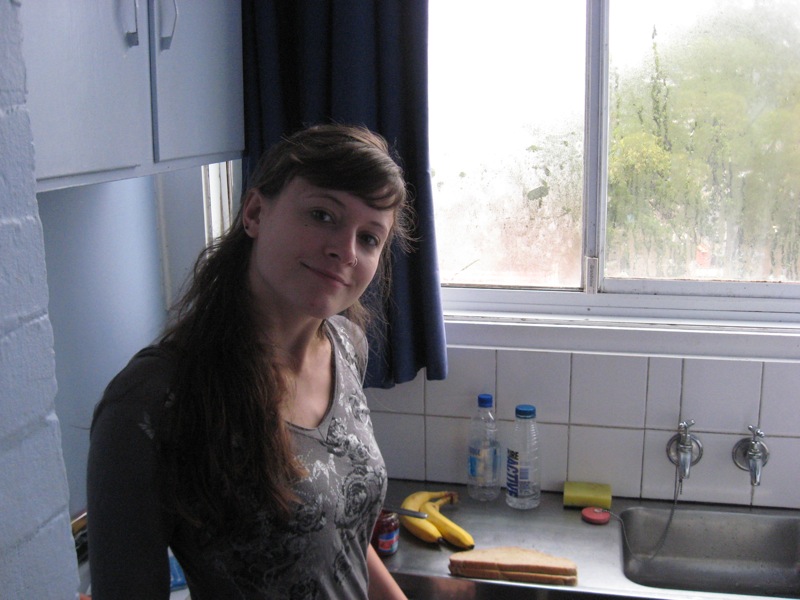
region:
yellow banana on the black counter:
[398, 482, 447, 546]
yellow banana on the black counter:
[427, 490, 479, 551]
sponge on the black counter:
[548, 474, 620, 507]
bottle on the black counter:
[506, 395, 538, 510]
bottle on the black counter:
[468, 392, 497, 499]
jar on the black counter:
[373, 503, 399, 551]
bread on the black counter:
[448, 544, 581, 587]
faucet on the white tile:
[665, 415, 708, 484]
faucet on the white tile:
[737, 426, 772, 490]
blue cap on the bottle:
[510, 399, 545, 421]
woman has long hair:
[87, 122, 410, 595]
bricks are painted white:
[5, 2, 85, 599]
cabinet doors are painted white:
[19, 2, 246, 194]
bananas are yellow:
[399, 483, 480, 557]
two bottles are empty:
[458, 386, 550, 514]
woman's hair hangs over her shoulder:
[149, 123, 406, 557]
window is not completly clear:
[603, 2, 796, 282]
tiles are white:
[362, 345, 799, 510]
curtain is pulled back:
[241, 3, 451, 389]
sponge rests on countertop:
[556, 472, 620, 512]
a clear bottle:
[462, 387, 508, 512]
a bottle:
[502, 402, 544, 506]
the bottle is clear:
[504, 404, 549, 506]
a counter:
[553, 529, 587, 550]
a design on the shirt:
[311, 460, 384, 529]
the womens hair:
[201, 384, 252, 453]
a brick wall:
[16, 427, 65, 543]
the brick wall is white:
[9, 438, 63, 540]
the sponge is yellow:
[567, 480, 609, 502]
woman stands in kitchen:
[86, 122, 418, 596]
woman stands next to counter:
[85, 120, 411, 599]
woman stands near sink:
[82, 120, 405, 599]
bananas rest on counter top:
[399, 482, 476, 560]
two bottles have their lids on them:
[465, 388, 548, 513]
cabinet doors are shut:
[18, 1, 253, 188]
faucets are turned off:
[668, 417, 776, 494]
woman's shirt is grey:
[82, 310, 386, 599]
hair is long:
[85, 116, 414, 540]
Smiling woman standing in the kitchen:
[84, 122, 410, 598]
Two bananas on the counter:
[402, 477, 474, 552]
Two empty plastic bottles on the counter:
[465, 387, 542, 507]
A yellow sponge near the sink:
[559, 478, 620, 511]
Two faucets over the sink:
[665, 417, 774, 486]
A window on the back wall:
[240, 0, 796, 308]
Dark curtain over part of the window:
[240, 3, 451, 387]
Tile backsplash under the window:
[368, 341, 796, 514]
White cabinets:
[9, 1, 246, 179]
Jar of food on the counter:
[372, 504, 401, 554]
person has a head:
[245, 147, 399, 315]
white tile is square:
[571, 353, 647, 429]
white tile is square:
[571, 422, 644, 498]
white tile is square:
[500, 351, 573, 421]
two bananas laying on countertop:
[398, 487, 479, 552]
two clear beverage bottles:
[459, 392, 548, 515]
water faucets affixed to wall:
[664, 419, 779, 488]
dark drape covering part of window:
[235, 0, 449, 395]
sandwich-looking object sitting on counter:
[439, 544, 580, 588]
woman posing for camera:
[82, 115, 415, 597]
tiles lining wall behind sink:
[367, 344, 797, 509]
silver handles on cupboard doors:
[115, 1, 183, 54]